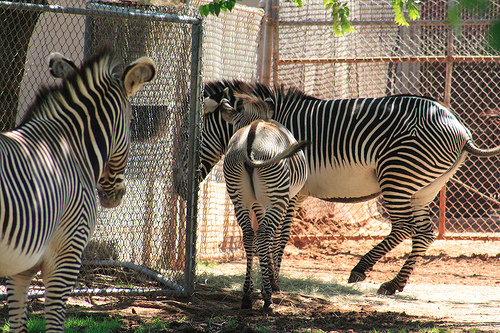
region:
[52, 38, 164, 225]
head of the zebra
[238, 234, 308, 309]
back legs of zebra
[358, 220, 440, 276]
two legs of zebra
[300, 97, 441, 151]
beautiful skin of zebra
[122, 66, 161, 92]
ear of the zebra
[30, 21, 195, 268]
a small fence around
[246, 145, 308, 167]
tail of the zebra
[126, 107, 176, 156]
a small window on wall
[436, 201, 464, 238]
an small iron rod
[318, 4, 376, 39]
a green beautiful leafs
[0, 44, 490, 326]
three zebras in enclosure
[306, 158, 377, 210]
white belly on zebra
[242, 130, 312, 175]
swinging tail on zebra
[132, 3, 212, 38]
pole on chain link fence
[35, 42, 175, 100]
ears on zebra head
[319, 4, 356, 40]
green leaves on trees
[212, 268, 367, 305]
shadow on ground under zebra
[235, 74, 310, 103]
mane on zebra neck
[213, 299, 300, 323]
dirt under zebra hooves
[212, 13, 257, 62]
sun reflection on metal fence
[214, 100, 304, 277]
this is a zebra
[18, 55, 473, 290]
they are three zebras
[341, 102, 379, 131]
the zebra has white and black strips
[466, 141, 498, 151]
this is the tail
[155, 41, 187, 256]
this is a fence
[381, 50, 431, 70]
this is a wire mess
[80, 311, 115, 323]
this is a grass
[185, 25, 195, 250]
this is a pole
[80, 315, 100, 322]
the grass is green in color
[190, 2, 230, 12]
this is a leaf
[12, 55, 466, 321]
these are some zebras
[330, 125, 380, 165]
the fur is black and white in color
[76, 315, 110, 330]
this is the grass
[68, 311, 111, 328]
the grass is green in color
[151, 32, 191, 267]
the fence is metallic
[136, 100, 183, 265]
the fence is big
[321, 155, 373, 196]
this is the zebra's belly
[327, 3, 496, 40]
these are tree leaves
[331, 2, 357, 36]
the leaves are green in color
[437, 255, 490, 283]
this is the ground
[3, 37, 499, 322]
three zebras in a pen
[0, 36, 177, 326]
a zebra with black stripes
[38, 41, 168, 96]
two big ears of zebra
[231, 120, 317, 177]
tail of zebra on side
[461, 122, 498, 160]
tail of zebra is up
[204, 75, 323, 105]
mane of zebra is black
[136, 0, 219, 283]
fence of pen is high and metal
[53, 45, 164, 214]
head of zebra has stripes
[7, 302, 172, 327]
patch of grass under zebra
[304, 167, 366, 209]
abdomen of zebra is bulky and white